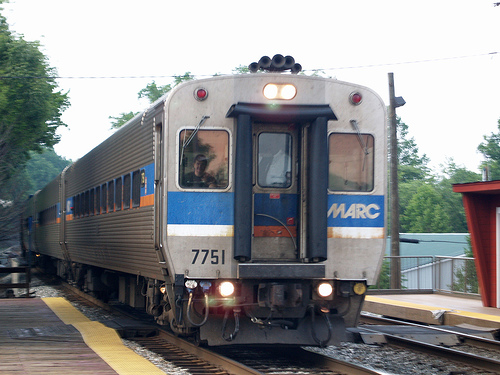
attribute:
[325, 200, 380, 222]
writing — white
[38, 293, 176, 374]
yellow line — thick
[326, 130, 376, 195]
window — rectangular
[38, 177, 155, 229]
stripe — orange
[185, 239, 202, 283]
number — black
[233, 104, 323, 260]
door — black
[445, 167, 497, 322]
building — red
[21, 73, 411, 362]
train — grey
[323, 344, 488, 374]
gravel — a pile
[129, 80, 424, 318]
metal fence — low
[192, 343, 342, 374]
tracks — brown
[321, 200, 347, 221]
letter m — white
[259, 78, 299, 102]
lights — a pair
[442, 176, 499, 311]
wood structure — red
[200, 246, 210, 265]
number "7" — black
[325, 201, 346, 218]
letter — white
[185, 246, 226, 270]
number — black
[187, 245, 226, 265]
numbers — black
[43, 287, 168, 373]
stripe — thick, yellow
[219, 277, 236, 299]
light — white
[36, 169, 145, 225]
windows — a row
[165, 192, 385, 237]
stripe — blue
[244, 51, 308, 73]
horn — black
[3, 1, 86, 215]
tree — green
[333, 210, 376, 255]
name — white